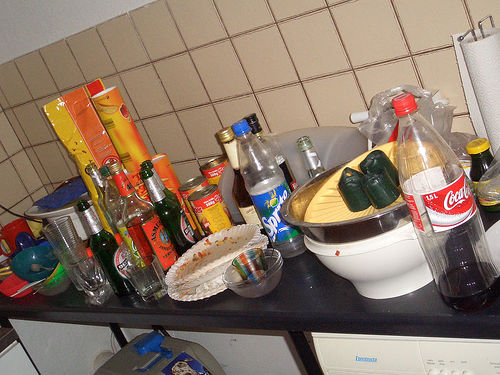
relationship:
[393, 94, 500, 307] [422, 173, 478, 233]
bottle of coca-cola